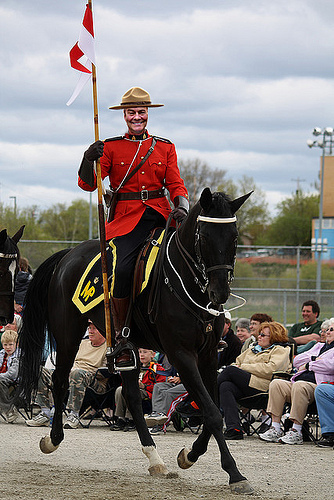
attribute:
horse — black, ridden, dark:
[19, 179, 273, 480]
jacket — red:
[79, 126, 206, 239]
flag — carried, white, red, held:
[48, 1, 110, 97]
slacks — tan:
[261, 370, 324, 443]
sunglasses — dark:
[262, 327, 294, 349]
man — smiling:
[75, 45, 196, 238]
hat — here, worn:
[100, 81, 145, 107]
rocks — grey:
[57, 465, 137, 493]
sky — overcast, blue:
[156, 16, 312, 203]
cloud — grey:
[19, 19, 92, 171]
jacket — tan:
[220, 331, 305, 387]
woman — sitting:
[147, 304, 301, 468]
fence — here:
[244, 246, 310, 348]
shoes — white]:
[242, 400, 311, 444]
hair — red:
[258, 311, 294, 356]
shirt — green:
[284, 307, 328, 344]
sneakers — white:
[268, 400, 316, 461]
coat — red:
[87, 158, 203, 220]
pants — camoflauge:
[30, 362, 111, 438]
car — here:
[247, 231, 275, 278]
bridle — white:
[162, 220, 261, 396]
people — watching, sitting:
[200, 298, 310, 411]